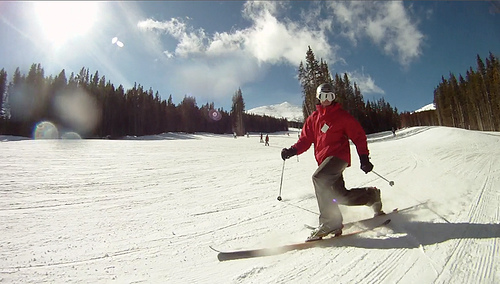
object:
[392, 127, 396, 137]
person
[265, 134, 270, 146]
person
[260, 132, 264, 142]
person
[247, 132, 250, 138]
person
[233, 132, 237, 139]
person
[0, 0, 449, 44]
skies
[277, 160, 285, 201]
skipole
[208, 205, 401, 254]
skiing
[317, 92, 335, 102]
goggles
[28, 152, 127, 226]
white snow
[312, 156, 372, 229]
pants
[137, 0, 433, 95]
cloud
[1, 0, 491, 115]
sky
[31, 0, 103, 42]
sun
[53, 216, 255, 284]
white snow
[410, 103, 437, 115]
mountain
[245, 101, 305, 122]
hill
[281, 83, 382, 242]
man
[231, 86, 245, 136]
tree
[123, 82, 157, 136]
tree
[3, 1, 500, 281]
scene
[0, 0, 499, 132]
background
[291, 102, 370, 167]
coat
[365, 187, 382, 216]
boot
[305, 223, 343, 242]
boot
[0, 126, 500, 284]
snow